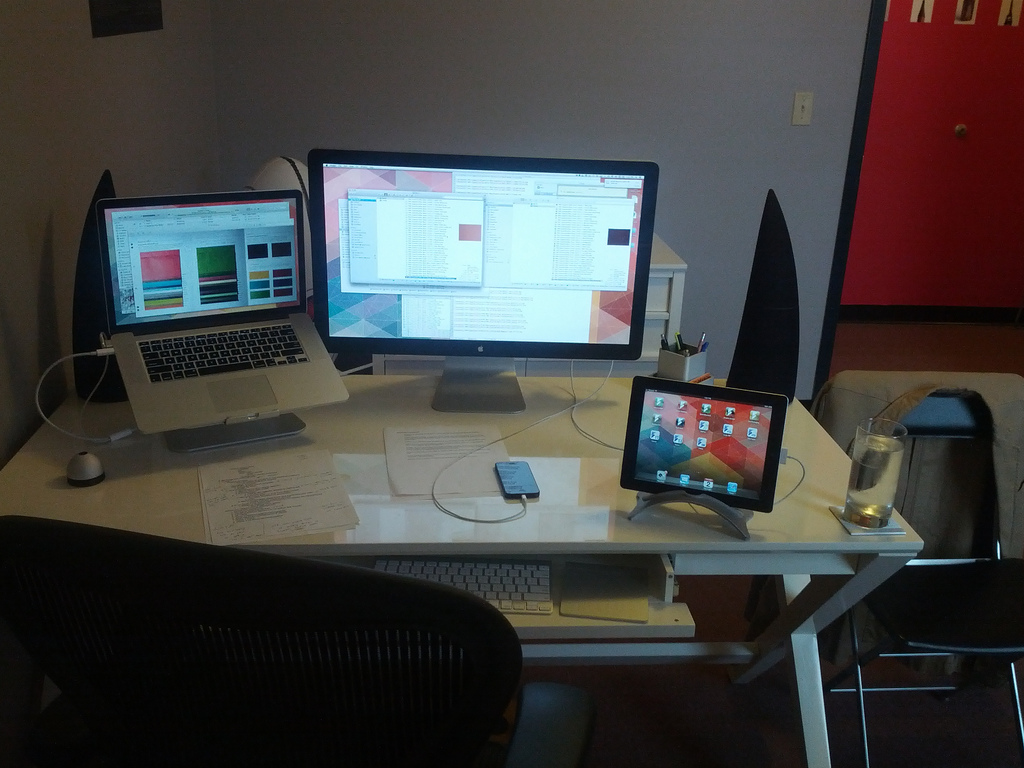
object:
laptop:
[95, 188, 350, 436]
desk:
[0, 375, 925, 555]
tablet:
[620, 376, 789, 515]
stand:
[629, 490, 751, 541]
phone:
[495, 461, 541, 499]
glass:
[843, 417, 908, 529]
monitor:
[306, 148, 660, 361]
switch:
[791, 91, 814, 126]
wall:
[0, 1, 869, 466]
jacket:
[846, 382, 946, 459]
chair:
[823, 556, 1022, 767]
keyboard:
[373, 560, 553, 615]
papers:
[198, 449, 360, 547]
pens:
[698, 331, 706, 353]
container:
[657, 341, 709, 381]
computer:
[309, 147, 660, 414]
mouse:
[68, 451, 106, 486]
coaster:
[829, 505, 906, 535]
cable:
[432, 359, 615, 523]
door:
[837, 0, 1024, 310]